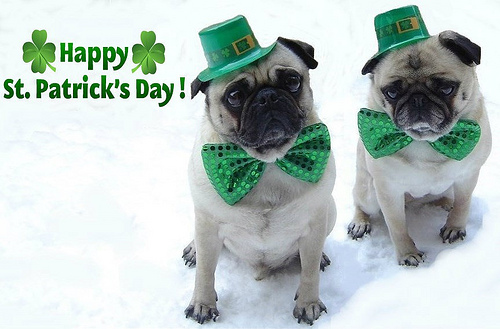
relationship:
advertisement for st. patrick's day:
[104, 28, 343, 327] [1, 69, 197, 114]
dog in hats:
[173, 9, 340, 328] [193, 14, 281, 84]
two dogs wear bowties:
[169, 1, 498, 324] [192, 101, 485, 211]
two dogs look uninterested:
[169, 1, 498, 324] [176, 49, 498, 172]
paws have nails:
[173, 204, 483, 323] [174, 306, 341, 327]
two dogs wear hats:
[169, 1, 498, 324] [188, 0, 435, 89]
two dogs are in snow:
[169, 1, 498, 324] [15, 182, 497, 325]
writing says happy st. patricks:
[1, 24, 215, 122] [2, 38, 186, 108]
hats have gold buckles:
[188, 0, 435, 89] [229, 11, 422, 58]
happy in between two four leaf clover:
[54, 35, 134, 75] [17, 22, 174, 78]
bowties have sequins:
[192, 101, 485, 211] [364, 114, 392, 145]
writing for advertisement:
[1, 24, 215, 122] [104, 28, 343, 327]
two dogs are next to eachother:
[169, 1, 498, 324] [188, 23, 499, 248]